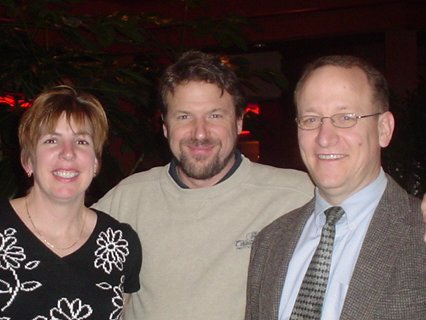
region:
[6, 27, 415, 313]
Three people posing for a picture.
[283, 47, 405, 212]
A man wearing glasses.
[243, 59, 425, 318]
A man wearing a grey suit.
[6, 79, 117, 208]
A woman with blonde hair.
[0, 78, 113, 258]
A woman wearing a gold necklace.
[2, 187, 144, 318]
A black and white shirt.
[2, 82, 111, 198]
A woman wearing earrings.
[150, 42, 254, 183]
A man with a beard.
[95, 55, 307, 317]
A man wearing a light colored shirt.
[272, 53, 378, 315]
A man wearing a tie.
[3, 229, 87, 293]
woman wearing black shirt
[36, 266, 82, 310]
black shirt with white flowers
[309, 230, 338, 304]
man wearing tan tie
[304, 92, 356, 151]
man wearing thin glasses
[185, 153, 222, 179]
man with dark goatee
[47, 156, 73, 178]
woman has a bright smile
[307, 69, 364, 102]
man with receding hairline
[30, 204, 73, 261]
woman wearing gold chain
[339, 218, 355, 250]
man in white dress shirt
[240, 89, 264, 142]
red glow behind man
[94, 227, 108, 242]
flower petal on shirt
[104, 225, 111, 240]
flower petal on shirt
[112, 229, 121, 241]
flower petal on shirt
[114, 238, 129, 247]
flower petal on shirt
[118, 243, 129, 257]
flower petal on shirt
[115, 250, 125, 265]
flower petal on shirt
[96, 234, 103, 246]
flower petal on shirt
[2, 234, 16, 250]
flower petal on shirt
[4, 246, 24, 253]
flower petal on shirt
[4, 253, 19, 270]
flower petal on shirt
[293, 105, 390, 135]
A pair of eyeglasses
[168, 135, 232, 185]
Facial hair on man's face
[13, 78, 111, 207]
A woman has red hair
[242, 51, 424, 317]
Man is wearing a suit and tie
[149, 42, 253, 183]
The man has brown hair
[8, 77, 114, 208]
The woman is smiling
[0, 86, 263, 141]
Red lights in the background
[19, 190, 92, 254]
Necklace around a lady's neck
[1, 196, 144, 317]
White patterns on a black shirt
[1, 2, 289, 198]
Green leaves on a tree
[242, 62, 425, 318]
Man wearing a gray jacket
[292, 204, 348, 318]
Tie around man's neck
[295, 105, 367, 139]
Eyeglasses on man's face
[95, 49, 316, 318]
Man wearing a tan sweater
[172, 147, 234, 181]
Hair on man's face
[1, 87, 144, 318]
Woman wearing a black shirt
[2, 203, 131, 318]
Floral pattern on woman's shirt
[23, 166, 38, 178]
Earring in the woman's ear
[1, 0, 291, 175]
Plants hanging in the background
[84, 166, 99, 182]
Earring in woman's ear